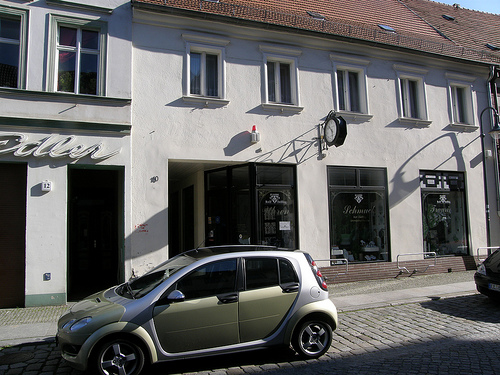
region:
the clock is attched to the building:
[285, 99, 374, 189]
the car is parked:
[63, 240, 337, 372]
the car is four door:
[102, 213, 358, 368]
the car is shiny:
[133, 248, 365, 365]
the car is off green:
[52, 241, 324, 372]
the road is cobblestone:
[380, 313, 453, 373]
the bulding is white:
[139, 94, 177, 129]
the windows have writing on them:
[343, 191, 407, 268]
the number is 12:
[32, 180, 62, 202]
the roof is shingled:
[410, 23, 454, 35]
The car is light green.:
[40, 232, 343, 366]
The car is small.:
[42, 237, 366, 374]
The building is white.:
[135, 7, 497, 247]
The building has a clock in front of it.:
[299, 104, 359, 161]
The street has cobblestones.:
[334, 288, 494, 367]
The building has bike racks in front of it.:
[318, 250, 498, 301]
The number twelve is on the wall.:
[26, 168, 63, 203]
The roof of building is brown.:
[145, 2, 496, 48]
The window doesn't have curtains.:
[40, 8, 123, 102]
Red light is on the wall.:
[237, 118, 274, 150]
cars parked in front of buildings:
[0, 0, 496, 365]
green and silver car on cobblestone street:
[6, 246, 496, 366]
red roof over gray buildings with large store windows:
[135, 5, 490, 290]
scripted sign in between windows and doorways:
[0, 2, 125, 302]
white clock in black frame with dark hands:
[310, 106, 345, 156]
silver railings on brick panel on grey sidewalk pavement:
[315, 245, 485, 306]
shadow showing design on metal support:
[250, 120, 325, 165]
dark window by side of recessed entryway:
[166, 161, 293, 252]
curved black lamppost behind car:
[470, 100, 495, 305]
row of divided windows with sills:
[181, 32, 474, 130]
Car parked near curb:
[49, 246, 339, 367]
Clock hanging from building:
[302, 106, 352, 161]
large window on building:
[407, 160, 474, 267]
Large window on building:
[323, 161, 395, 266]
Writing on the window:
[340, 194, 372, 224]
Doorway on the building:
[195, 159, 275, 269]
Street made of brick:
[2, 292, 499, 371]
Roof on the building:
[131, 1, 498, 66]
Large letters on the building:
[0, 129, 118, 174]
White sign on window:
[273, 214, 298, 234]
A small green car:
[68, 260, 342, 358]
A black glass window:
[244, 164, 296, 245]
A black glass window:
[324, 164, 389, 274]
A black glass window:
[427, 174, 471, 248]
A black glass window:
[177, 43, 222, 93]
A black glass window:
[255, 48, 300, 118]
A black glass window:
[41, 15, 112, 85]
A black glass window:
[0, 3, 21, 100]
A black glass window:
[330, 63, 374, 117]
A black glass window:
[391, 58, 429, 125]